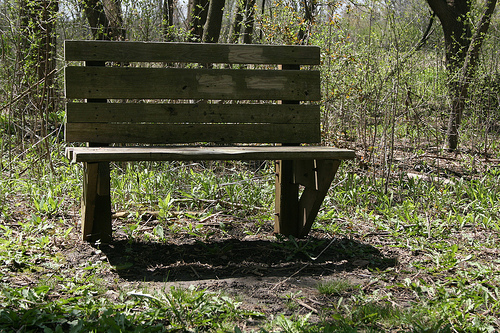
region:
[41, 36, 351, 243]
A brown bench on dirt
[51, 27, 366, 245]
Bench is made of wood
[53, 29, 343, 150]
Top of the bench has four uneven planks of wood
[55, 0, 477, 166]
Trees are behind the bench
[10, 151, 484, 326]
Green, leafy plants grow under the bench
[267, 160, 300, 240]
There are silver bolts in the bench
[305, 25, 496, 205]
Thin brown stalks of plants with green leaves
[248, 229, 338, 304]
Brown sticks lay on the ground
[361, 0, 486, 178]
There are smaller plants underneath the trees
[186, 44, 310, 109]
There are two planks on the bench that are worn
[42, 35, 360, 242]
A wooden bench in the foreground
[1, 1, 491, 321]
Photo was taken outdoors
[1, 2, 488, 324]
Photo was taken in the daytime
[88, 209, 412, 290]
Bench is casting a shadow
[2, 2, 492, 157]
Trees are in the background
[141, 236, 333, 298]
A dirt patch on the ground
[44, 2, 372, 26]
The sky is behind the trees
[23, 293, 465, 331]
Plants are on the ground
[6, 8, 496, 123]
Small leaves are growing on trees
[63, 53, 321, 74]
Small gap is in the park bench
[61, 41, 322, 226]
the bench is old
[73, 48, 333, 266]
Bench is attached ot the ground.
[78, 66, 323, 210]
bench is brown color.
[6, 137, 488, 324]
Dried leaves and grass are in the ground.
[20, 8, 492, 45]
Woods are brown color.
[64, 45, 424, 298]
Shadow falls on ground.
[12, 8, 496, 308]
Day time picture.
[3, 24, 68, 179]
Leaves are green color.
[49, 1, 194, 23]
Sky is white color.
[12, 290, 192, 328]
Grass are green color.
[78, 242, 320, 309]
Ground is brown color.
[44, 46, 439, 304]
an old looking chair